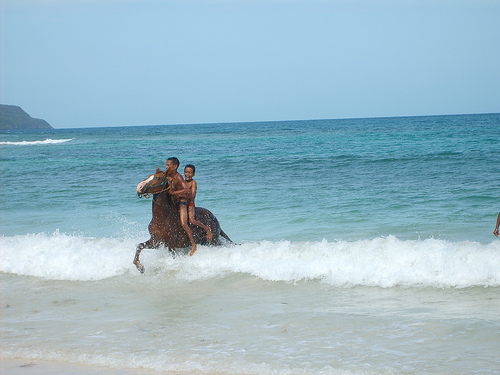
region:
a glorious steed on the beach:
[126, 152, 241, 276]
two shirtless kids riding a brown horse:
[165, 158, 216, 248]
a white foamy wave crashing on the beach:
[1, 228, 497, 285]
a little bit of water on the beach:
[0, 279, 498, 371]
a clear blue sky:
[5, 0, 496, 113]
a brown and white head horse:
[135, 169, 167, 196]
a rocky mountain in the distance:
[1, 100, 58, 134]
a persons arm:
[494, 216, 499, 234]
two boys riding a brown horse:
[124, 148, 227, 263]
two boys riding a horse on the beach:
[117, 153, 241, 263]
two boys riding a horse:
[130, 154, 245, 277]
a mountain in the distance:
[0, 102, 53, 130]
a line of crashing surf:
[0, 229, 498, 292]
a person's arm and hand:
[491, 205, 498, 241]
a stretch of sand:
[2, 362, 219, 374]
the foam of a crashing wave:
[0, 136, 75, 146]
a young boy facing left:
[156, 154, 197, 258]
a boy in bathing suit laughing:
[179, 163, 216, 245]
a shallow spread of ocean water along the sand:
[1, 270, 498, 373]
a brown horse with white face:
[132, 168, 239, 280]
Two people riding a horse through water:
[136, 145, 253, 288]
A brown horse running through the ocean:
[122, 169, 252, 297]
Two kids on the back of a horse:
[158, 150, 218, 247]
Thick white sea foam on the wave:
[235, 230, 495, 297]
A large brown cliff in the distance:
[2, 102, 67, 137]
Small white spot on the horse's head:
[137, 173, 155, 195]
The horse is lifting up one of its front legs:
[130, 235, 170, 279]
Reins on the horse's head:
[139, 170, 171, 196]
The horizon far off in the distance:
[97, 111, 497, 128]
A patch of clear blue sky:
[68, 23, 378, 102]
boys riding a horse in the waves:
[102, 139, 252, 299]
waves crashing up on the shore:
[246, 225, 411, 372]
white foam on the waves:
[270, 224, 428, 296]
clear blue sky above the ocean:
[194, 56, 414, 165]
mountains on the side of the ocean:
[3, 99, 81, 172]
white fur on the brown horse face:
[126, 170, 171, 202]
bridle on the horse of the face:
[129, 163, 171, 202]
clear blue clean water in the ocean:
[253, 119, 399, 231]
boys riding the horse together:
[157, 146, 222, 266]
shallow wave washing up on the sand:
[3, 311, 85, 371]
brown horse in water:
[112, 150, 226, 289]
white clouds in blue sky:
[288, 15, 325, 72]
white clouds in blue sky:
[388, 37, 440, 77]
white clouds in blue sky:
[321, 55, 357, 87]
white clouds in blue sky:
[202, 58, 227, 78]